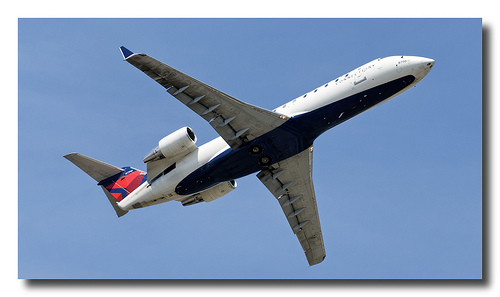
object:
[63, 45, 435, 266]
airplane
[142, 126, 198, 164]
engine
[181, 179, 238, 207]
engine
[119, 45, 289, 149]
wing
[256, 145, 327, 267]
wing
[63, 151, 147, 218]
tail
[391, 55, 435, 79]
nose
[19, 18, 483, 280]
sky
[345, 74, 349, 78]
window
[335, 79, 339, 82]
window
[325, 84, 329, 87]
window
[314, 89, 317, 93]
window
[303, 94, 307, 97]
window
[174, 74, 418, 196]
bottom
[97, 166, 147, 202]
design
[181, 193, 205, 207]
ending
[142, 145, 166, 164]
tip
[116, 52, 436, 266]
fuselage